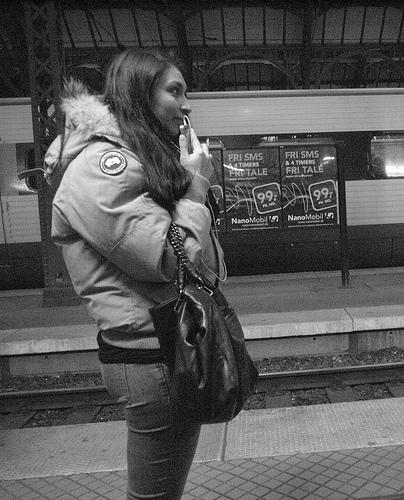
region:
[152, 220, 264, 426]
Black purse hanging from the woman's arm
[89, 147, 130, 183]
Logo patch on the woman's coat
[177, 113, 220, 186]
Phone in the woman's hand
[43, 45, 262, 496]
Woman standing on the street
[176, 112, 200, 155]
Phone with a white jack plugged into it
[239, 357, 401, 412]
Train tracks on the ground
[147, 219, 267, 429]
A black bag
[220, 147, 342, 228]
Advertisement on the train platform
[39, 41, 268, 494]
woman standing on train platform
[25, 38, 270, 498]
woman holding a black handbag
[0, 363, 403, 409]
Train track behind girl holding the purse.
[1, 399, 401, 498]
Platform above train tracks where girl is standing.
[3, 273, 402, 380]
Platform above the train tracks across from where the girl is standing.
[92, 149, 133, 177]
Circle patch on girl's coat.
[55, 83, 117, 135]
Fur on hood of the coat the girl is wearing.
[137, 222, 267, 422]
Big black purse that the girl is holding.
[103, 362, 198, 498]
Jeans that the girl is wearing.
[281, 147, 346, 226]
Second advertisement sign across from the girl.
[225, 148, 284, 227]
First advertisement across from where the girl is standing.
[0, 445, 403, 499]
Medium sized tiles where the girl is standing.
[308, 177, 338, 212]
99 cents written on the window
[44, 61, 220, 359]
a woman wearing a jacket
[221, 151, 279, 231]
advertising on the window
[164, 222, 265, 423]
a dark colored purse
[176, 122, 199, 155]
a cell phone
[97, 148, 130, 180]
a round patch on a jacket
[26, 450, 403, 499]
a square pattern on the sidewalk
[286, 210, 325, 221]
The words Nano Mobile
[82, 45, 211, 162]
a young girl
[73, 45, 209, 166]
a girl holding a cell phone to her face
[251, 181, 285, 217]
small white square with wording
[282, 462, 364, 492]
black criss cross tiles on ground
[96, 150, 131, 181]
round logo on woman's jacket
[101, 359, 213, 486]
tight black pants on woman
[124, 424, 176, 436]
large crease in woman's pant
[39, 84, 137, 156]
fur collar on woman's jacket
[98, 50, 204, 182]
black hair on woman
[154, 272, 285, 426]
large black shiny bag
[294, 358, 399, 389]
large black train track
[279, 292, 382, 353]
white train platform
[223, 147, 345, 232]
Two identical advertisements in the background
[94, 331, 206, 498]
Jeans on a woman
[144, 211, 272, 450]
A dark bag on the woman's arm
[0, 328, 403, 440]
Train tracks beside the woman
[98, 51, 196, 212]
Long hair on the woman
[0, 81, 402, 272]
Train going by in the background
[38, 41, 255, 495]
Woman waiting for her train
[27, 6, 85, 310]
Metal support beam in the background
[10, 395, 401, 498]
Sidewalk beside train tracks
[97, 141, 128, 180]
Patch on woman's jacket